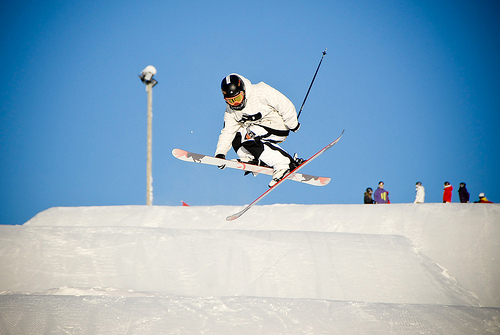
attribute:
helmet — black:
[221, 73, 245, 96]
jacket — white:
[208, 82, 300, 155]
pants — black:
[234, 119, 297, 173]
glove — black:
[210, 149, 228, 162]